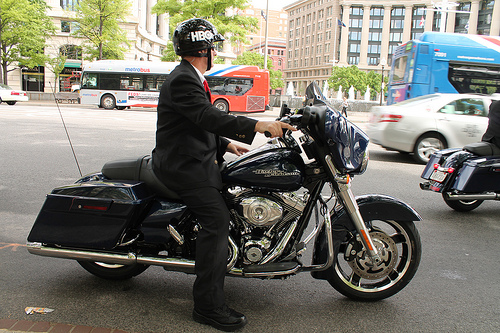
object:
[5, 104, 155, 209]
road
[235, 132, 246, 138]
buttons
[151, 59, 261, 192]
coat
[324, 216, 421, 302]
front wheel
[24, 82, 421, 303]
bike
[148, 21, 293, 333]
man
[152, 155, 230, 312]
dress pants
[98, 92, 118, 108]
wheel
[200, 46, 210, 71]
strap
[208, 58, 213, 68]
chin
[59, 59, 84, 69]
green awning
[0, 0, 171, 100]
building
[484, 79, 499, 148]
man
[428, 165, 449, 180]
plate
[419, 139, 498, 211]
motorcycle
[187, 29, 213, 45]
white writing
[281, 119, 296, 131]
fingers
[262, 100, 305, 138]
handlebar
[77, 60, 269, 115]
bus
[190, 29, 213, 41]
lettering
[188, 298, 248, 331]
shoe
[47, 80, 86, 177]
antenna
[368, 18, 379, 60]
windows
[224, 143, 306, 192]
tank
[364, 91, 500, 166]
car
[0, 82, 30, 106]
car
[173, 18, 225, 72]
helmet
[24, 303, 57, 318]
trash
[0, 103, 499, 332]
ground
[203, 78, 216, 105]
necktie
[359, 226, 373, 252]
orange reflector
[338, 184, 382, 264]
metal piece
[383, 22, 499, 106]
bus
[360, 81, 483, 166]
silver car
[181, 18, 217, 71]
head